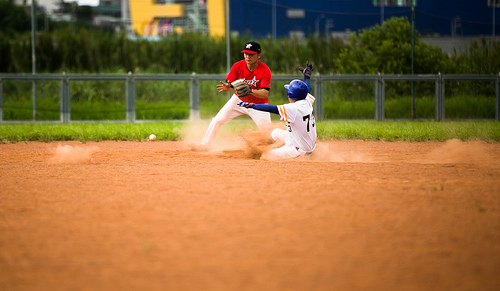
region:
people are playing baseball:
[198, 43, 316, 160]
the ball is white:
[148, 132, 156, 139]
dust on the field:
[51, 113, 465, 164]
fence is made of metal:
[0, 72, 498, 122]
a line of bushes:
[4, 30, 499, 92]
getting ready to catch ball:
[196, 43, 271, 153]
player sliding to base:
[235, 64, 318, 161]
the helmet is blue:
[282, 80, 305, 95]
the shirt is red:
[227, 60, 271, 102]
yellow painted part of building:
[130, 0, 225, 37]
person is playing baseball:
[278, 81, 324, 170]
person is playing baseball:
[223, 47, 267, 134]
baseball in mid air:
[144, 130, 162, 145]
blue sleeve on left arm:
[243, 101, 279, 114]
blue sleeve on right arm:
[304, 72, 321, 89]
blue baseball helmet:
[288, 78, 305, 98]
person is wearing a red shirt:
[226, 51, 268, 93]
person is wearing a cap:
[238, 39, 263, 65]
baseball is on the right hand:
[229, 65, 271, 102]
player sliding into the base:
[243, 82, 334, 167]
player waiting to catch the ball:
[188, 36, 279, 156]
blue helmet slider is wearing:
[284, 81, 309, 98]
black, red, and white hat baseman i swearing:
[239, 42, 259, 56]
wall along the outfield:
[7, 64, 494, 118]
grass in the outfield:
[7, 121, 497, 140]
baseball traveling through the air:
[143, 133, 157, 145]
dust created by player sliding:
[168, 113, 499, 169]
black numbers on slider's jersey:
[300, 112, 317, 133]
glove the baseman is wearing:
[226, 82, 250, 98]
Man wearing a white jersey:
[234, 59, 341, 159]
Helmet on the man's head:
[277, 72, 311, 101]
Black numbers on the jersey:
[294, 106, 320, 137]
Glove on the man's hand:
[295, 62, 315, 82]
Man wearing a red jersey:
[194, 40, 276, 155]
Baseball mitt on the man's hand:
[222, 73, 257, 98]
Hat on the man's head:
[237, 38, 264, 63]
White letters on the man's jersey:
[235, 69, 263, 89]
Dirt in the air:
[159, 111, 358, 178]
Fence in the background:
[0, 55, 499, 149]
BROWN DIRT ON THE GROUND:
[282, 220, 407, 270]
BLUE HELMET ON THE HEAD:
[286, 80, 306, 92]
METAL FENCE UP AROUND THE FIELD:
[380, 71, 431, 116]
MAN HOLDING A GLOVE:
[231, 80, 246, 91]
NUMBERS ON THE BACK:
[300, 105, 315, 125]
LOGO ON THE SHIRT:
[245, 71, 255, 82]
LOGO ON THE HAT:
[243, 41, 250, 47]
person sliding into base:
[238, 60, 316, 160]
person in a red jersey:
[188, 39, 273, 150]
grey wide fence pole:
[58, 69, 68, 116]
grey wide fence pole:
[123, 69, 135, 121]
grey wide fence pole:
[188, 76, 199, 113]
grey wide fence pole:
[373, 72, 383, 118]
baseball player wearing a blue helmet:
[236, 61, 317, 161]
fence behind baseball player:
[2, 70, 499, 124]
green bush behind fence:
[333, 15, 458, 99]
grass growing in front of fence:
[0, 119, 499, 141]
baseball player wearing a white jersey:
[236, 61, 318, 158]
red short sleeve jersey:
[222, 60, 272, 105]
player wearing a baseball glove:
[198, 41, 274, 150]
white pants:
[201, 93, 273, 148]